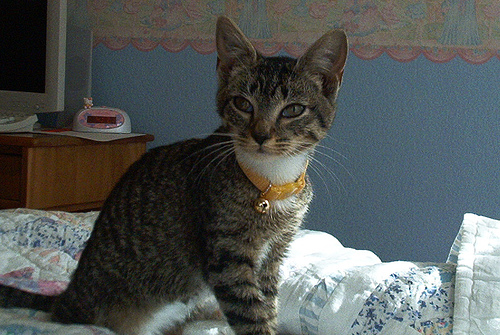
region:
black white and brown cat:
[1, 23, 346, 333]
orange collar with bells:
[232, 143, 314, 212]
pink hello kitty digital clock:
[75, 97, 132, 132]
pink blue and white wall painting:
[91, 5, 496, 65]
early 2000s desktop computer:
[0, 2, 62, 113]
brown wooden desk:
[3, 132, 146, 208]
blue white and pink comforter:
[1, 210, 498, 334]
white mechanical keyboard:
[0, 111, 36, 132]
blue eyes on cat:
[230, 95, 259, 118]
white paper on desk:
[36, 128, 146, 143]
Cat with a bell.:
[191, 35, 351, 263]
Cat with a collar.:
[197, 14, 375, 253]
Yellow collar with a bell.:
[199, 125, 333, 216]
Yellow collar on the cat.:
[183, 16, 363, 269]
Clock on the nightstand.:
[63, 83, 149, 162]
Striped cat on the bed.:
[111, 36, 382, 319]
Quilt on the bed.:
[259, 194, 457, 333]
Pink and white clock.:
[57, 79, 184, 176]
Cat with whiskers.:
[176, 19, 371, 255]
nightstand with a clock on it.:
[70, 100, 165, 232]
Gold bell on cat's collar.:
[249, 183, 297, 233]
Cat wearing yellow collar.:
[234, 150, 314, 217]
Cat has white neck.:
[244, 154, 284, 174]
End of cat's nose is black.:
[251, 130, 270, 150]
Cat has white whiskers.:
[188, 120, 369, 185]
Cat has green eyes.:
[216, 84, 322, 114]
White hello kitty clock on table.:
[72, 94, 154, 154]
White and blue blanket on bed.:
[304, 258, 446, 332]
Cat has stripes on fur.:
[91, 141, 221, 279]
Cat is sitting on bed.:
[60, 165, 315, 326]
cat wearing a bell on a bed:
[38, 13, 357, 333]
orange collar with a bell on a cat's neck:
[221, 150, 311, 222]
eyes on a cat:
[221, 84, 321, 132]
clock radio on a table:
[66, 91, 140, 138]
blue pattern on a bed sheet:
[347, 245, 464, 333]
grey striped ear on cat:
[302, 26, 355, 88]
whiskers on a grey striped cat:
[292, 137, 375, 209]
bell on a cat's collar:
[243, 195, 277, 217]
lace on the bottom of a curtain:
[348, 40, 498, 66]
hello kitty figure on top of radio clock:
[77, 94, 98, 114]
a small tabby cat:
[2, 14, 351, 334]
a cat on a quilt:
[0, 10, 495, 330]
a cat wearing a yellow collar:
[0, 10, 345, 332]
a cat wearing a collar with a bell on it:
[0, 10, 345, 333]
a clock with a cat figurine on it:
[70, 95, 125, 130]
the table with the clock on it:
[0, 125, 155, 210]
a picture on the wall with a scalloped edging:
[90, 0, 495, 60]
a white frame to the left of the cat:
[0, 0, 65, 110]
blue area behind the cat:
[90, 40, 495, 255]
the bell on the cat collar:
[250, 195, 270, 212]